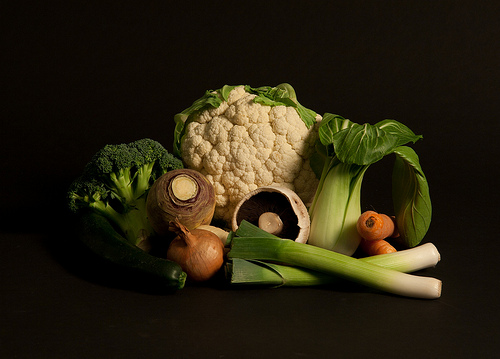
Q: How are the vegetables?
A: Fresh and crispy.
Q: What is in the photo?
A: An assortment of vegetables.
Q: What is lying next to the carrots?
A: A stalk of celery.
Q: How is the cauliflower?
A: White.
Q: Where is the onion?
A: Next to the cucumber.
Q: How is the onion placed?
A: Upright.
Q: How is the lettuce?
A: Green.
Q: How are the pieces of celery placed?
A: On top of another.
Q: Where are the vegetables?
A: On the table.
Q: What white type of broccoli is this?
A: Cauliflower.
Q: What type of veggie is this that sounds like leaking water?
A: Leaks.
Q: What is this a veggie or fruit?
A: Veggie.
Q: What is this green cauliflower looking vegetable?
A: Broccoli.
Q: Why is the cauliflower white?
A: Genetics.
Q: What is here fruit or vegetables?
A: Vegetables.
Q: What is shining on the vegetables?
A: Light.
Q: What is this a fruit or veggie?
A: Veggies.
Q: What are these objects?
A: Vegetables.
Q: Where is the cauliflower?
A: In the back.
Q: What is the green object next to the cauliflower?
A: Broccoli.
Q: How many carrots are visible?
A: Two.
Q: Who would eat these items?
A: A vegetarian.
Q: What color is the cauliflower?
A: White.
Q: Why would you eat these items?
A: To be healthy.